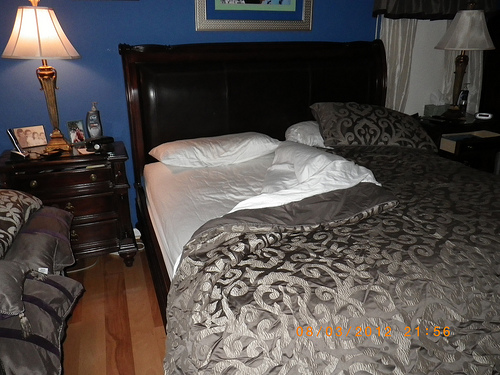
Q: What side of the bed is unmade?
A: Left side.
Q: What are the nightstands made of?
A: Dark brown wood.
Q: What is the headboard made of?
A: Leather.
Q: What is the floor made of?
A: Wood.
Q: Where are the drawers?
A: Under the nightstands.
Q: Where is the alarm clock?
A: On the right nightstand.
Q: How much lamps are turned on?
A: One.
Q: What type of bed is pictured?
A: A sleigh bed.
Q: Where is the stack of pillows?
A: On the floor.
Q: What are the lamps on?
A: Nightstands.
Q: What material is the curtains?
A: Satin-like.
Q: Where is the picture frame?
A: Left nightstand.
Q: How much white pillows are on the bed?
A: Two.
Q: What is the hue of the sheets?
A: White.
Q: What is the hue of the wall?
A: Blue.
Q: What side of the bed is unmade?
A: Left side.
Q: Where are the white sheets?
A: On the bed.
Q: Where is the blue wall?
A: Behind the headboard.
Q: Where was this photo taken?
A: In a bedroom.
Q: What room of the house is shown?
A: Bedroom.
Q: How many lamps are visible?
A: Two.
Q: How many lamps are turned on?
A: One.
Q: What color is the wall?
A: Blue.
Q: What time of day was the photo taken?
A: Night.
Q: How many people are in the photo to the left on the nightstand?
A: Four.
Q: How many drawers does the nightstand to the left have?
A: Three.